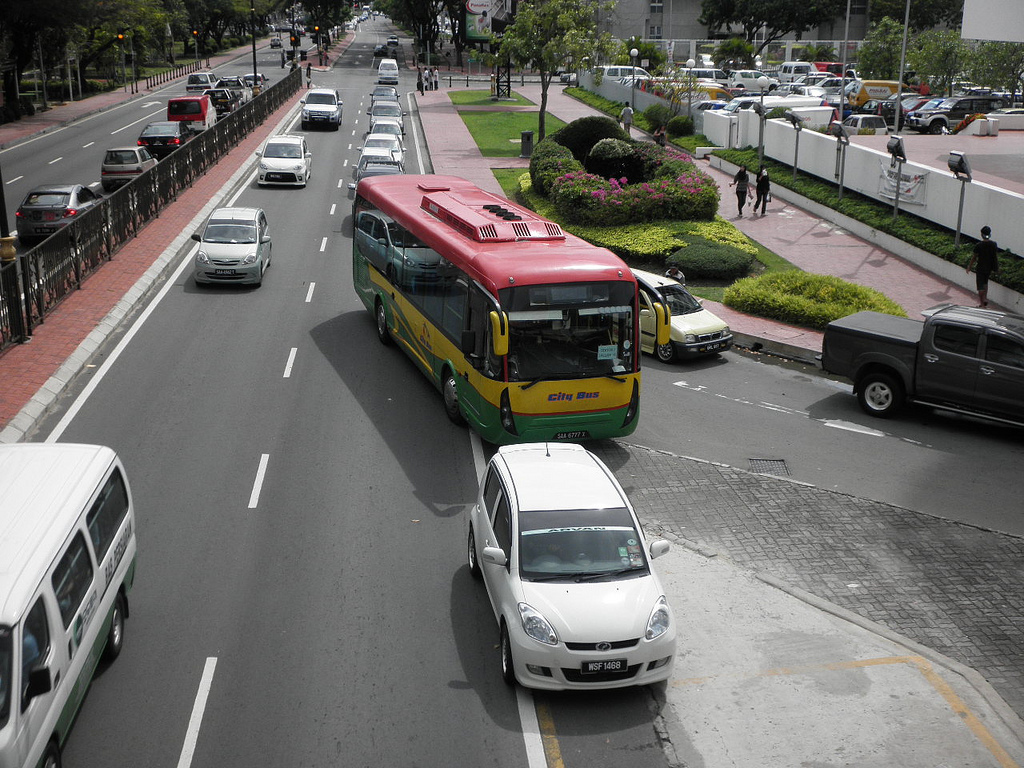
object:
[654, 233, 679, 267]
mirrors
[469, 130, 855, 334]
bus